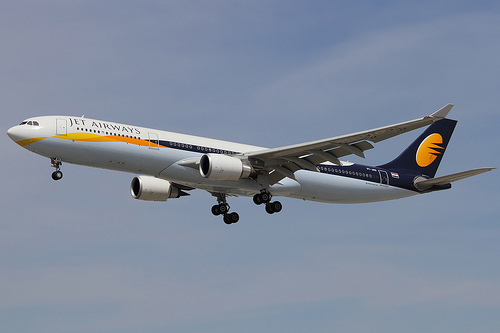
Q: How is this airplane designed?
A: White, yellow and blue colors.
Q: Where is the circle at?
A: Tail of plane.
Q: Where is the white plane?
A: In sky.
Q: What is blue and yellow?
A: Plane's tail.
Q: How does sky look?
A: Sky is blue.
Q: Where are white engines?
A: Under plane.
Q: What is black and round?
A: The tires.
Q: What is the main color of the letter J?
A: Black.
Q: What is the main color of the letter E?
A: Black.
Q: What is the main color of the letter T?
A: Black.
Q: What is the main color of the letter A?
A: Black.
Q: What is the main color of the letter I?
A: Black.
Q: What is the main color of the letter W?
A: Black.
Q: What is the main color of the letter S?
A: White.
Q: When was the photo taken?
A: Daytime.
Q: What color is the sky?
A: Blue.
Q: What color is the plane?
A: White, yellow, and navy.